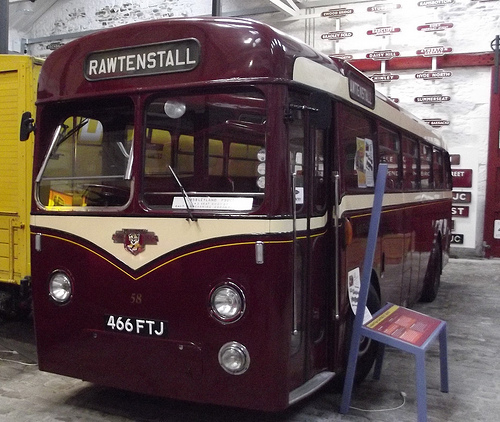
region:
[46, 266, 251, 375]
headlights on the bus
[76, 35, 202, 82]
a sign on the front of the bus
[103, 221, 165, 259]
a symbol on the front of the bus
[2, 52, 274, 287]
a yellow train car visible beside the bus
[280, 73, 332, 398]
the door to the interior of the bus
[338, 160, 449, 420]
a purple display next to the bus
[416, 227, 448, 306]
a rear wheel on the bus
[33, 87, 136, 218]
a front window on the bus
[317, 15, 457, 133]
signs hang on the wall behind the bus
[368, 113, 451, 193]
windows on the side of the bus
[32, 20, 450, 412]
maroon city bus parked in a garage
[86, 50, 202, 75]
title on the front of the bus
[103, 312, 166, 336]
numbers and letters on the front of the bus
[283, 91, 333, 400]
front door of a bus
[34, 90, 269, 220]
front glass windows of the bus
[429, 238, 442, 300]
back left wheel of a bus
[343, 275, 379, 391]
front left wheel of a bus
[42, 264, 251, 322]
front headlights of a bus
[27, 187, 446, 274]
white stripe desing on the bus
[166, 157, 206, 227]
wipers on the bus window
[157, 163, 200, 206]
wipers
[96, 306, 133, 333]
numbers on the bus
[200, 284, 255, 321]
a headlight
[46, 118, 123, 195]
a windshield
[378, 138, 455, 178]
windows on the bus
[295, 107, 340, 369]
the door on the bus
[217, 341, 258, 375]
clear headlights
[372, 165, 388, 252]
a blue pole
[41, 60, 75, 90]
a maroon bus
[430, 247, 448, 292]
back tire to the bus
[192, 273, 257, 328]
light on front of bus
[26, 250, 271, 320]
two lights on the bus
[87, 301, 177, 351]
numbers and letters on the bus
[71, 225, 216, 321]
red and white bus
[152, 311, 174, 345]
the letter J on bus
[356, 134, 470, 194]
windows on side of bus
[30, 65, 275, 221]
windows on front of bus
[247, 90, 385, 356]
door on side of bus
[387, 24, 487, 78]
wall in the background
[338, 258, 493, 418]
item next to the bus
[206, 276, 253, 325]
a headlight on the bus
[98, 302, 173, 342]
a black license plate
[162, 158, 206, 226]
a windshield wiper on the bus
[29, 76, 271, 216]
the windshield of the bus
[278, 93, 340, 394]
the doors of the bus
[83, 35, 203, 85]
a display on the bus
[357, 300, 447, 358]
information about the exhibit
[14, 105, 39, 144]
a side view mirror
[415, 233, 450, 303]
a black bus tire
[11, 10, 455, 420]
a red and white bus